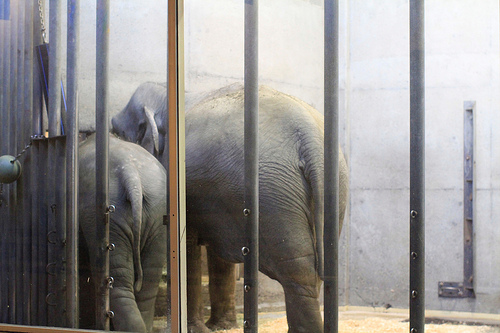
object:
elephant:
[111, 82, 349, 333]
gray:
[274, 119, 307, 158]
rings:
[241, 246, 250, 256]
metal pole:
[241, 0, 257, 333]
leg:
[280, 248, 324, 333]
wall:
[61, 0, 496, 321]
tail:
[121, 178, 144, 292]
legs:
[84, 219, 148, 332]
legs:
[166, 236, 214, 333]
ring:
[242, 208, 250, 217]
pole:
[408, 0, 425, 331]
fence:
[2, 0, 499, 333]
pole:
[323, 0, 340, 333]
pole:
[167, 0, 188, 331]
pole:
[96, 0, 110, 333]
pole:
[64, 6, 81, 329]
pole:
[47, 0, 68, 325]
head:
[110, 83, 174, 151]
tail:
[298, 132, 328, 280]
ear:
[111, 92, 147, 143]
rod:
[65, 0, 79, 330]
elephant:
[77, 131, 169, 332]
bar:
[462, 101, 476, 301]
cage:
[0, 0, 499, 333]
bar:
[243, 0, 260, 333]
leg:
[205, 248, 238, 332]